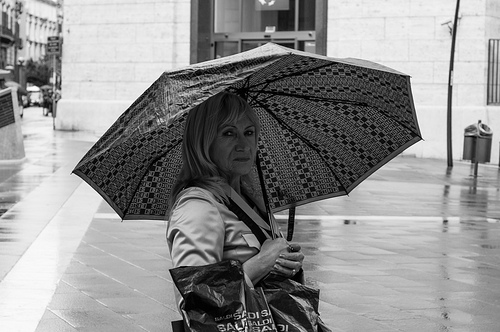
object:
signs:
[35, 29, 66, 139]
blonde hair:
[173, 90, 260, 195]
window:
[212, 3, 319, 38]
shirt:
[164, 178, 287, 306]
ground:
[367, 198, 410, 230]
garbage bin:
[474, 121, 492, 164]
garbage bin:
[460, 121, 475, 161]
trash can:
[463, 120, 493, 162]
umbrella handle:
[246, 92, 282, 239]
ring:
[291, 268, 297, 276]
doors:
[211, 29, 317, 56]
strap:
[178, 185, 267, 245]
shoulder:
[166, 182, 227, 257]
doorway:
[190, 2, 328, 62]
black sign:
[0, 91, 16, 127]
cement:
[1, 156, 33, 198]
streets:
[0, 117, 494, 328]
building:
[0, 5, 500, 172]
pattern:
[82, 239, 119, 281]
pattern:
[431, 258, 480, 314]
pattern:
[394, 166, 444, 199]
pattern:
[317, 220, 367, 267]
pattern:
[134, 277, 162, 315]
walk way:
[0, 105, 499, 330]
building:
[0, 0, 24, 84]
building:
[25, 1, 60, 67]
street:
[19, 104, 56, 120]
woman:
[160, 85, 309, 328]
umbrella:
[69, 42, 426, 224]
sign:
[45, 35, 62, 55]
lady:
[165, 90, 302, 330]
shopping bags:
[166, 253, 328, 329]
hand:
[271, 244, 305, 278]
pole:
[471, 160, 480, 177]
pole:
[52, 50, 57, 130]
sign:
[263, 23, 279, 34]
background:
[4, 1, 499, 169]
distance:
[2, 0, 499, 162]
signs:
[47, 36, 60, 42]